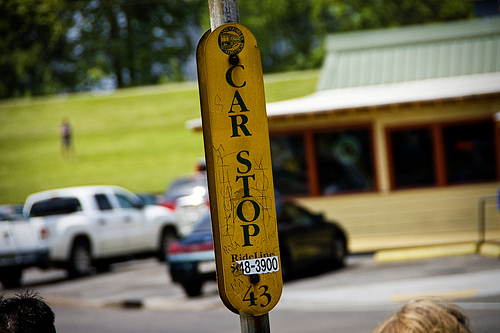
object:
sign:
[193, 21, 296, 321]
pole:
[206, 1, 274, 332]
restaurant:
[187, 26, 500, 254]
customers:
[331, 125, 376, 189]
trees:
[3, 2, 142, 99]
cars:
[22, 179, 186, 279]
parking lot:
[4, 235, 500, 332]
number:
[236, 277, 280, 307]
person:
[59, 115, 75, 157]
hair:
[2, 289, 55, 330]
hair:
[378, 296, 471, 332]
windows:
[381, 111, 500, 199]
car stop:
[213, 63, 267, 250]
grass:
[1, 59, 317, 202]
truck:
[0, 196, 63, 291]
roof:
[176, 22, 499, 132]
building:
[186, 16, 500, 253]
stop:
[225, 144, 263, 252]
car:
[166, 204, 353, 297]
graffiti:
[216, 148, 236, 257]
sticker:
[235, 256, 293, 281]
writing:
[228, 62, 259, 253]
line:
[388, 290, 487, 304]